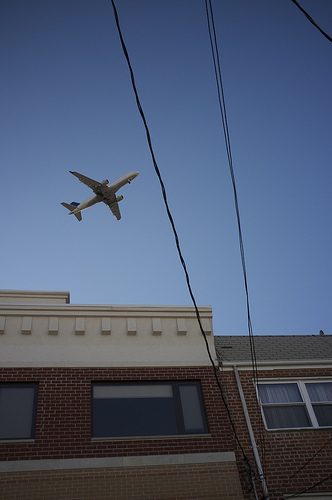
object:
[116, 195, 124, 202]
engine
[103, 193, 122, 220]
wing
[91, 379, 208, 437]
window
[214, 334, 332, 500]
building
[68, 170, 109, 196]
wing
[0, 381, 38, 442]
window frames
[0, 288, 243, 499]
building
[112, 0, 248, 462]
power line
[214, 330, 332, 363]
roof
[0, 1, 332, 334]
sky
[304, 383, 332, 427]
window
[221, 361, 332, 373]
gutter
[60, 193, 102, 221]
fins airplane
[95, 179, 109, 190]
engine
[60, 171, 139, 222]
airplane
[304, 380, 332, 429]
windows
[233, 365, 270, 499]
pole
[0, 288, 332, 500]
building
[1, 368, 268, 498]
wall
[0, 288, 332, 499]
neighborhood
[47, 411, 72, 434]
brick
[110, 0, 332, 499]
wires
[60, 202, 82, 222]
fins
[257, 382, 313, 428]
curtain